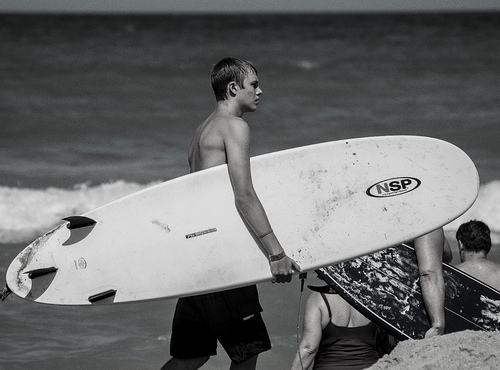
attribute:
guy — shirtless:
[194, 46, 271, 115]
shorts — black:
[162, 273, 274, 363]